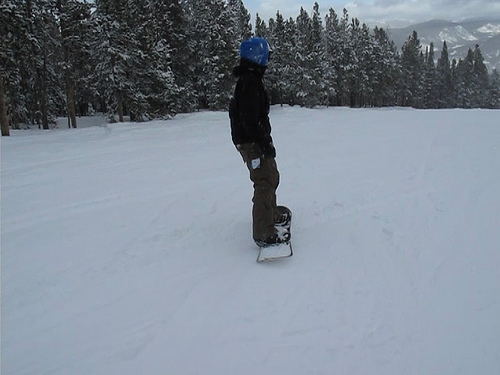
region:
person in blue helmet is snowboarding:
[228, 35, 296, 261]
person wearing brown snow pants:
[238, 145, 285, 242]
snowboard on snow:
[258, 203, 298, 259]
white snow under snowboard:
[0, 103, 499, 373]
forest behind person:
[0, 1, 499, 129]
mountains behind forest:
[380, 17, 499, 74]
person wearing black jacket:
[228, 55, 272, 145]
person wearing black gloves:
[258, 135, 279, 162]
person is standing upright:
[231, 32, 290, 244]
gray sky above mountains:
[242, 1, 498, 36]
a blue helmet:
[236, 31, 275, 67]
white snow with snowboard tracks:
[100, 274, 277, 368]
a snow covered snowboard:
[247, 204, 299, 265]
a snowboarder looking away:
[212, 32, 312, 267]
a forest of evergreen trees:
[18, 10, 483, 99]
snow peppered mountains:
[366, 11, 497, 76]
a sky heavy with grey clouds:
[343, 0, 461, 19]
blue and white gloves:
[246, 146, 266, 167]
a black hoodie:
[222, 68, 277, 138]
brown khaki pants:
[223, 135, 291, 240]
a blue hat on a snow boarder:
[232, 30, 277, 67]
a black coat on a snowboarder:
[216, 65, 281, 150]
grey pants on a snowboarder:
[230, 130, 290, 235]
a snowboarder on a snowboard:
[225, 30, 295, 270]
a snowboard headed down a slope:
[250, 190, 305, 265]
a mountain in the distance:
[392, 20, 493, 60]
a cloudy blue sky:
[245, 0, 496, 21]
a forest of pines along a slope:
[2, 0, 497, 115]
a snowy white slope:
[4, 109, 496, 370]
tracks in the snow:
[97, 171, 221, 300]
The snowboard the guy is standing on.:
[255, 191, 298, 272]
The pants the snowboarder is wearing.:
[237, 140, 279, 240]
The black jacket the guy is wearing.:
[225, 57, 270, 147]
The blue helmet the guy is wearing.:
[240, 26, 270, 56]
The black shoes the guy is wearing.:
[260, 201, 290, 246]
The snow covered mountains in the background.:
[373, 21, 493, 76]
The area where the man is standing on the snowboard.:
[202, 167, 343, 307]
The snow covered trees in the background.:
[10, 10, 495, 135]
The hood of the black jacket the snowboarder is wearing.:
[223, 60, 250, 80]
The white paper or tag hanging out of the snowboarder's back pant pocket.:
[241, 157, 262, 177]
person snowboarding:
[225, 31, 300, 272]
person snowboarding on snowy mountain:
[236, 33, 299, 270]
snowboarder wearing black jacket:
[223, 73, 270, 138]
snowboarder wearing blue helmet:
[232, 34, 274, 57]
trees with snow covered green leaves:
[16, 1, 126, 118]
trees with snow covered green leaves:
[124, 14, 223, 106]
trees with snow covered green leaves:
[289, 36, 489, 110]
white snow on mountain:
[14, 146, 209, 322]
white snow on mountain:
[308, 120, 470, 313]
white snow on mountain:
[92, 276, 404, 338]